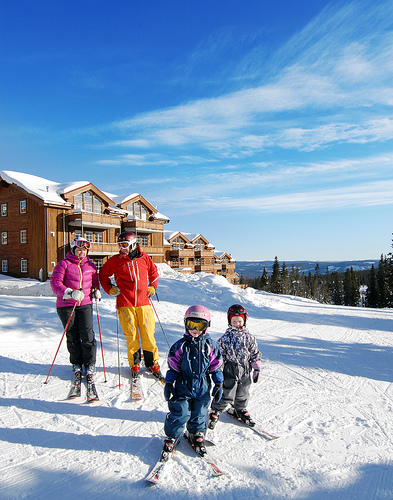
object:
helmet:
[68, 234, 89, 254]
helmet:
[225, 301, 246, 327]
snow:
[1, 262, 391, 498]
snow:
[2, 165, 90, 209]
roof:
[2, 167, 170, 223]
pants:
[221, 364, 252, 413]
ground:
[280, 315, 370, 437]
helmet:
[116, 218, 140, 260]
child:
[152, 300, 220, 457]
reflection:
[0, 426, 199, 487]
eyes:
[232, 318, 243, 325]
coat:
[100, 247, 158, 314]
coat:
[216, 319, 269, 379]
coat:
[165, 334, 226, 400]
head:
[182, 303, 212, 334]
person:
[213, 299, 260, 415]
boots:
[211, 384, 256, 419]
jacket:
[166, 331, 224, 383]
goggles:
[184, 315, 206, 331]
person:
[51, 234, 102, 379]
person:
[99, 228, 160, 372]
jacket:
[49, 255, 99, 304]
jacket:
[215, 325, 262, 365]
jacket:
[97, 242, 159, 305]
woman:
[50, 238, 108, 388]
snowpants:
[117, 298, 165, 378]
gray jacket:
[216, 328, 263, 380]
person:
[163, 304, 223, 457]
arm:
[247, 332, 262, 383]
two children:
[144, 303, 278, 484]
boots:
[158, 426, 219, 461]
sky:
[0, 0, 392, 259]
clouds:
[0, 0, 392, 261]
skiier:
[96, 222, 179, 384]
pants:
[167, 379, 211, 442]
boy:
[209, 304, 261, 420]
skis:
[207, 418, 277, 439]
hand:
[252, 359, 263, 383]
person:
[159, 296, 224, 462]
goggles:
[224, 303, 251, 317]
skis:
[135, 420, 233, 489]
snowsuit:
[156, 326, 226, 453]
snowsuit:
[209, 324, 259, 415]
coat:
[47, 250, 100, 314]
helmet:
[183, 302, 214, 337]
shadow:
[239, 329, 391, 386]